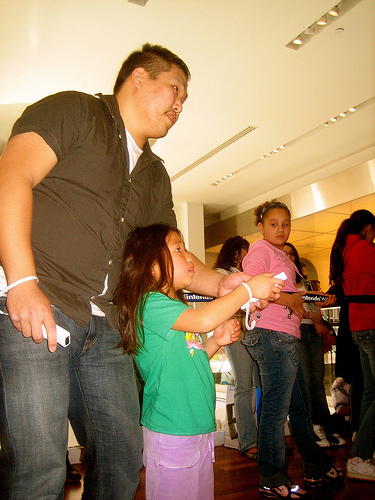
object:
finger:
[228, 337, 240, 342]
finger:
[267, 292, 280, 297]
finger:
[271, 287, 280, 292]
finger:
[272, 277, 284, 285]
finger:
[232, 323, 241, 332]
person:
[114, 221, 284, 498]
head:
[252, 199, 292, 246]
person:
[270, 242, 346, 499]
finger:
[42, 315, 57, 353]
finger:
[30, 320, 44, 344]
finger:
[21, 318, 33, 341]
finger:
[10, 319, 22, 331]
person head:
[119, 224, 195, 295]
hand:
[6, 271, 58, 353]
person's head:
[113, 43, 191, 138]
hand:
[244, 272, 283, 303]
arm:
[150, 280, 252, 332]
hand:
[213, 317, 241, 345]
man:
[0, 42, 268, 498]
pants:
[0, 295, 144, 498]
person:
[240, 198, 307, 499]